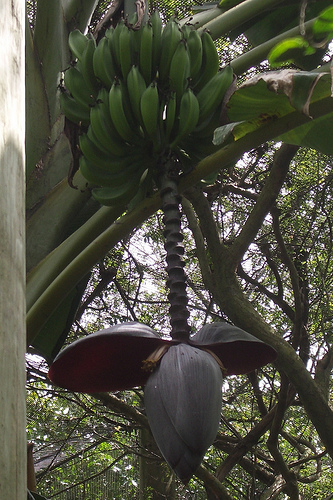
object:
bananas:
[58, 81, 91, 127]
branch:
[170, 164, 332, 378]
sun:
[0, 0, 27, 158]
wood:
[0, 0, 28, 500]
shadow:
[181, 147, 295, 287]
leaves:
[227, 69, 333, 163]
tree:
[26, 0, 330, 500]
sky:
[23, 1, 332, 466]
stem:
[159, 167, 195, 340]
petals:
[45, 310, 166, 395]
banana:
[141, 77, 161, 147]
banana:
[109, 77, 141, 155]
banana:
[168, 40, 190, 101]